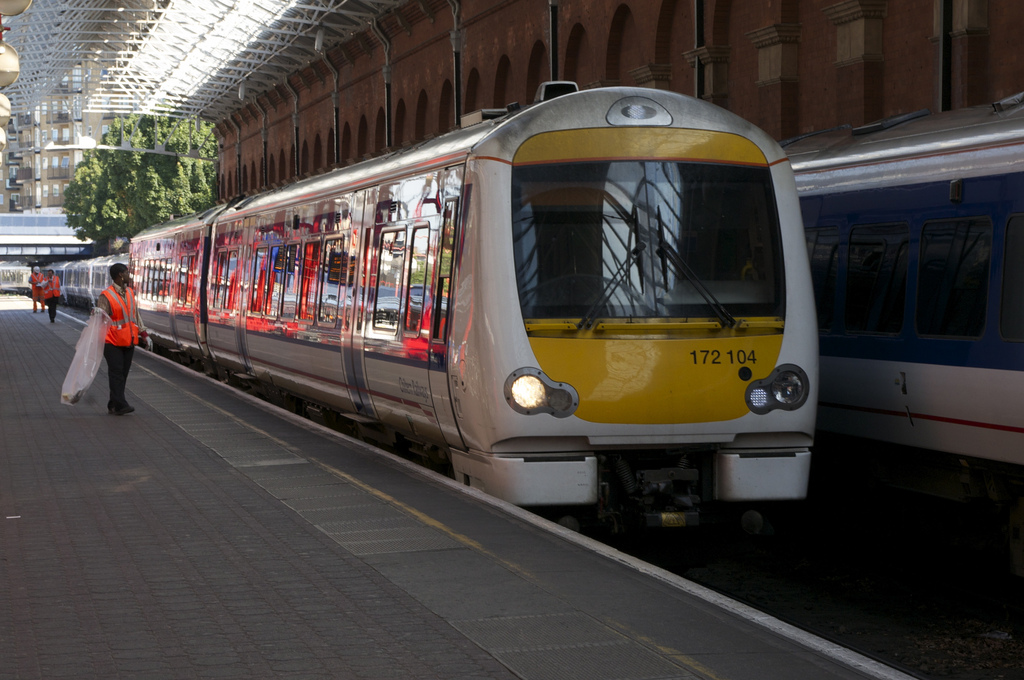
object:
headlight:
[501, 362, 548, 421]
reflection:
[359, 153, 469, 365]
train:
[117, 67, 831, 525]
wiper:
[559, 220, 658, 331]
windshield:
[496, 127, 794, 331]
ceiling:
[13, 8, 314, 127]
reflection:
[586, 146, 693, 317]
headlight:
[600, 93, 674, 133]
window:
[496, 157, 791, 343]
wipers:
[668, 231, 739, 319]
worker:
[43, 253, 62, 325]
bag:
[50, 300, 113, 415]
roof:
[17, 0, 356, 117]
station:
[8, 9, 1023, 675]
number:
[745, 339, 762, 369]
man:
[41, 269, 189, 410]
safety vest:
[95, 289, 139, 356]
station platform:
[2, 289, 947, 668]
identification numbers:
[676, 330, 701, 370]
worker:
[23, 253, 45, 313]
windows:
[421, 169, 462, 336]